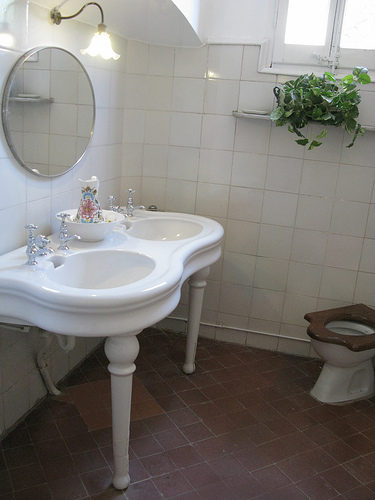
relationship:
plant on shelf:
[272, 65, 370, 151] [233, 105, 375, 132]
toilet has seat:
[300, 295, 374, 412] [299, 299, 374, 353]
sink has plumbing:
[5, 201, 228, 494] [8, 321, 80, 406]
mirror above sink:
[3, 45, 97, 180] [5, 201, 228, 494]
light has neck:
[49, 2, 124, 68] [60, 3, 107, 32]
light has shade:
[49, 2, 124, 68] [79, 31, 120, 63]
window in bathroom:
[263, 1, 374, 82] [2, 2, 373, 499]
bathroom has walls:
[2, 2, 373, 499] [5, 4, 374, 358]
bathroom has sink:
[2, 2, 373, 499] [5, 201, 228, 494]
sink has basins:
[5, 201, 228, 494] [53, 209, 193, 294]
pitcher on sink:
[76, 176, 107, 225] [5, 201, 228, 494]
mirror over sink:
[3, 45, 97, 180] [5, 201, 228, 494]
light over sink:
[49, 2, 124, 68] [5, 201, 228, 494]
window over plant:
[263, 1, 374, 82] [272, 65, 370, 151]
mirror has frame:
[3, 45, 97, 180] [8, 43, 98, 180]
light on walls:
[49, 2, 124, 68] [5, 4, 374, 358]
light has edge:
[49, 2, 124, 68] [81, 47, 117, 60]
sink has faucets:
[5, 201, 228, 494] [16, 186, 145, 268]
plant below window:
[272, 65, 370, 151] [263, 1, 374, 82]